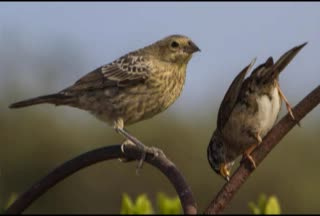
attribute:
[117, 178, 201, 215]
plants — green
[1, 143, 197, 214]
branch — curved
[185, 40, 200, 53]
beak — brown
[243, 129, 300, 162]
branch — straight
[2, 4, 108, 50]
skies — clear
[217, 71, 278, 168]
bird — perched, upside down